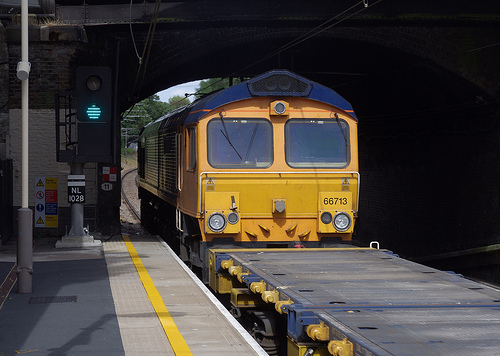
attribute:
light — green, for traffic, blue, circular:
[83, 102, 106, 121]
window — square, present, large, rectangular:
[280, 116, 353, 173]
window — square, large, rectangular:
[206, 117, 276, 170]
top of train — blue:
[141, 67, 357, 128]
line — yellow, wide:
[119, 228, 194, 354]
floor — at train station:
[0, 233, 269, 355]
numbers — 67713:
[319, 192, 350, 207]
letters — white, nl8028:
[68, 184, 87, 204]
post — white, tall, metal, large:
[10, 0, 40, 299]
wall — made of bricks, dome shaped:
[0, 27, 126, 236]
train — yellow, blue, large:
[134, 59, 374, 256]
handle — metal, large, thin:
[191, 164, 367, 215]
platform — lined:
[0, 0, 270, 355]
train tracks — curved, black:
[115, 161, 153, 238]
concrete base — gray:
[16, 205, 37, 298]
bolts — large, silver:
[216, 255, 352, 356]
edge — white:
[157, 233, 273, 356]